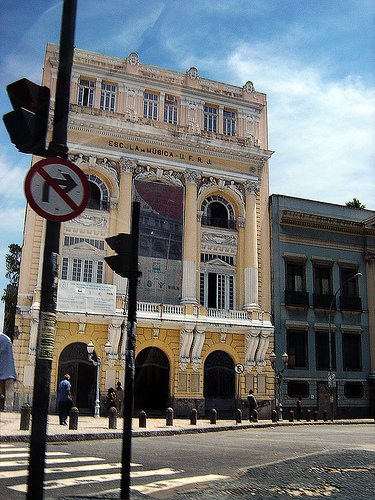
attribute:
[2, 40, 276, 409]
building — yellow, light colored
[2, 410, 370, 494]
street — paved, rough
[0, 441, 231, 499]
lines — white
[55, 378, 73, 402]
shirt — blue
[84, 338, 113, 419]
street light — white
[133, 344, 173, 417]
doorway — open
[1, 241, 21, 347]
tree — green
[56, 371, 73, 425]
man — walking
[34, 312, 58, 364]
sign — glued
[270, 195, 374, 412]
building — dark colored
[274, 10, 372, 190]
sky — blue